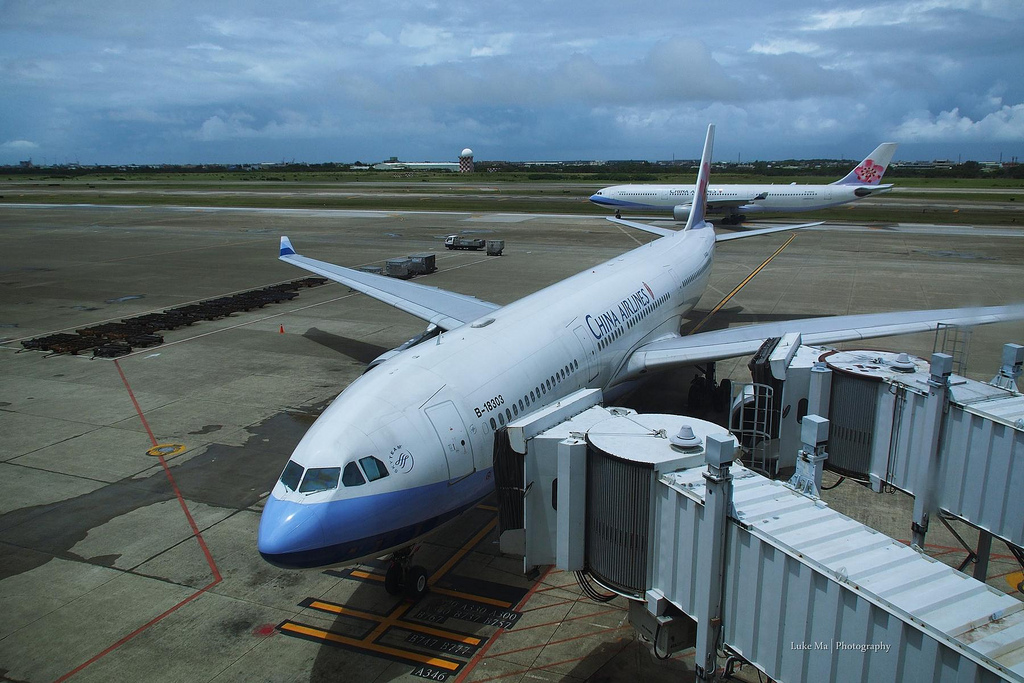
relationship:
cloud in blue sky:
[748, 28, 824, 65] [0, 0, 1024, 165]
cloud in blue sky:
[890, 101, 1011, 162] [0, 0, 1024, 165]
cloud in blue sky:
[391, 19, 458, 67] [0, 0, 1024, 165]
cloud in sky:
[370, 19, 502, 74] [2, 3, 1020, 198]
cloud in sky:
[890, 95, 1016, 152] [2, 3, 1020, 198]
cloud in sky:
[199, 112, 334, 154] [2, 3, 1020, 198]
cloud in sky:
[4, 119, 43, 169] [2, 3, 1020, 198]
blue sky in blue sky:
[0, 0, 1024, 165] [0, 0, 1024, 165]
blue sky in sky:
[0, 0, 1024, 165] [8, 3, 1020, 176]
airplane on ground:
[255, 124, 1022, 570] [8, 167, 1020, 673]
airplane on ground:
[254, 145, 1021, 573] [8, 167, 1020, 673]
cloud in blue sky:
[748, 28, 833, 65] [0, 0, 1024, 165]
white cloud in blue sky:
[804, 4, 911, 35] [7, 0, 1010, 167]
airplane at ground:
[255, 124, 1022, 570] [0, 170, 1024, 683]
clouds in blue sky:
[175, 106, 495, 154] [0, 0, 1024, 165]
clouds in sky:
[250, 39, 376, 98] [2, 3, 1020, 198]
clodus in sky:
[451, 33, 875, 127] [2, 3, 1020, 198]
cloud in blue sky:
[75, 18, 534, 124] [0, 0, 1024, 165]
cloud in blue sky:
[375, 61, 620, 146] [0, 0, 1024, 165]